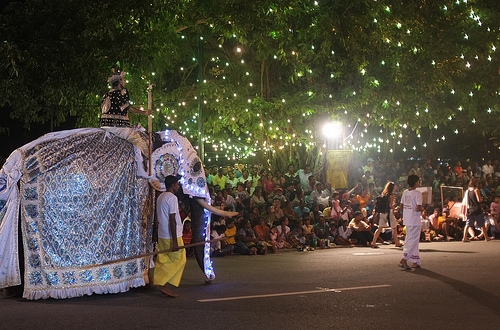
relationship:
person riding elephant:
[98, 64, 154, 181] [0, 126, 239, 301]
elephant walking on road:
[14, 48, 254, 315] [2, 233, 497, 329]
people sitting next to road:
[179, 165, 499, 253] [2, 233, 497, 329]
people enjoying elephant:
[202, 142, 499, 254] [0, 126, 239, 301]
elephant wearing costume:
[0, 126, 239, 301] [3, 129, 217, 296]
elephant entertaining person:
[0, 126, 239, 301] [275, 215, 296, 236]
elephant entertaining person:
[0, 126, 239, 301] [339, 222, 351, 239]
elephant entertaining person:
[0, 126, 239, 301] [291, 230, 311, 250]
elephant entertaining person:
[0, 126, 239, 301] [247, 187, 266, 204]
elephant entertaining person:
[0, 126, 239, 301] [268, 186, 287, 202]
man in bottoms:
[149, 175, 187, 300] [151, 236, 187, 289]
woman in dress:
[399, 171, 432, 266] [401, 188, 421, 260]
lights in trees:
[193, 48, 472, 170] [4, 2, 498, 185]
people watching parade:
[226, 172, 366, 257] [18, 86, 458, 279]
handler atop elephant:
[96, 71, 149, 180] [0, 126, 239, 301]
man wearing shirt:
[149, 173, 189, 300] [155, 193, 188, 240]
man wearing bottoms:
[149, 173, 189, 300] [146, 234, 195, 287]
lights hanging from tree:
[147, 26, 484, 150] [131, 1, 485, 187]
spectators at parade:
[182, 157, 498, 251] [2, 60, 457, 327]